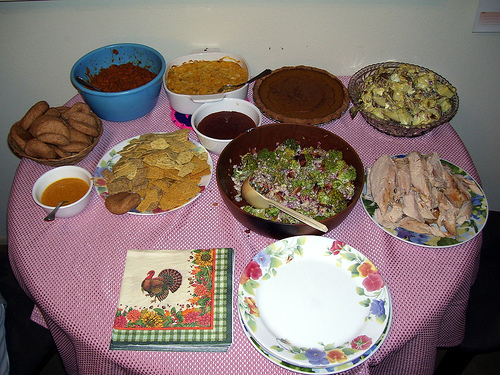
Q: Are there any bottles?
A: No, there are no bottles.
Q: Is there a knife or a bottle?
A: No, there are no bottles or knives.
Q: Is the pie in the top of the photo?
A: Yes, the pie is in the top of the image.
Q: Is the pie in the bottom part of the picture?
A: No, the pie is in the top of the image.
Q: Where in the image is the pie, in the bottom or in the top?
A: The pie is in the top of the image.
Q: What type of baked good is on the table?
A: The food is a pie.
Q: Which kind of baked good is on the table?
A: The food is a pie.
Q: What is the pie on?
A: The pie is on the table.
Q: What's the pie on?
A: The pie is on the table.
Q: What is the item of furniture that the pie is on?
A: The piece of furniture is a table.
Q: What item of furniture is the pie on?
A: The pie is on the table.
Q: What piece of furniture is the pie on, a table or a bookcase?
A: The pie is on a table.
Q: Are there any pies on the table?
A: Yes, there is a pie on the table.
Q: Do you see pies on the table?
A: Yes, there is a pie on the table.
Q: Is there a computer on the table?
A: No, there is a pie on the table.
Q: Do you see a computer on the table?
A: No, there is a pie on the table.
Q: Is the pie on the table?
A: Yes, the pie is on the table.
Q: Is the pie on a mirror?
A: No, the pie is on the table.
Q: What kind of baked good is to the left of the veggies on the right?
A: The food is a pie.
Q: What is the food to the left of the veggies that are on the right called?
A: The food is a pie.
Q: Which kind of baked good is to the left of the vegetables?
A: The food is a pie.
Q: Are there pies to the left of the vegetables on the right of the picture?
A: Yes, there is a pie to the left of the vegetables.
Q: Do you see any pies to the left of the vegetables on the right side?
A: Yes, there is a pie to the left of the vegetables.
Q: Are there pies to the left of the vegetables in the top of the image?
A: Yes, there is a pie to the left of the vegetables.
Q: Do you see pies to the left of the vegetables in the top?
A: Yes, there is a pie to the left of the vegetables.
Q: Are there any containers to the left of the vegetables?
A: No, there is a pie to the left of the vegetables.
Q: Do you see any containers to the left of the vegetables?
A: No, there is a pie to the left of the vegetables.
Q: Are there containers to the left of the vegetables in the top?
A: No, there is a pie to the left of the vegetables.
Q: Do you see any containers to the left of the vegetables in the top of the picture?
A: No, there is a pie to the left of the vegetables.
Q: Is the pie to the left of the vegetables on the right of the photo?
A: Yes, the pie is to the left of the vegetables.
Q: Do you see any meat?
A: Yes, there is meat.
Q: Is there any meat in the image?
A: Yes, there is meat.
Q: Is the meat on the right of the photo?
A: Yes, the meat is on the right of the image.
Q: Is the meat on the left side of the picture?
A: No, the meat is on the right of the image.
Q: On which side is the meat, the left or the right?
A: The meat is on the right of the image.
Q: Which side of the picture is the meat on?
A: The meat is on the right of the image.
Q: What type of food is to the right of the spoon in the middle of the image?
A: The food is meat.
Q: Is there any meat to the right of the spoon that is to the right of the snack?
A: Yes, there is meat to the right of the spoon.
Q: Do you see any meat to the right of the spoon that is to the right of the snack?
A: Yes, there is meat to the right of the spoon.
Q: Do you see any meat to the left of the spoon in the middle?
A: No, the meat is to the right of the spoon.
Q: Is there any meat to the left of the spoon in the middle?
A: No, the meat is to the right of the spoon.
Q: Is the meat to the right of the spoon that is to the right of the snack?
A: Yes, the meat is to the right of the spoon.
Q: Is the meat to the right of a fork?
A: No, the meat is to the right of the spoon.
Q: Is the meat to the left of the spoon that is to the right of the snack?
A: No, the meat is to the right of the spoon.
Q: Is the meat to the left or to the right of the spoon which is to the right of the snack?
A: The meat is to the right of the spoon.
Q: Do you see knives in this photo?
A: No, there are no knives.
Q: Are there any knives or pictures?
A: No, there are no knives or pictures.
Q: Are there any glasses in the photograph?
A: No, there are no glasses.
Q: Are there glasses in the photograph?
A: No, there are no glasses.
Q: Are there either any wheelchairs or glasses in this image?
A: No, there are no glasses or wheelchairs.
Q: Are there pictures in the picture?
A: No, there are no pictures.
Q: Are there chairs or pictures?
A: No, there are no pictures or chairs.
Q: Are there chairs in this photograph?
A: No, there are no chairs.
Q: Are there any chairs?
A: No, there are no chairs.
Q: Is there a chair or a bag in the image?
A: No, there are no chairs or bags.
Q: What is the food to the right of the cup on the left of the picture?
A: The food is a snack.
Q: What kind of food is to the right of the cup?
A: The food is a snack.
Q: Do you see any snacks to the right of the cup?
A: Yes, there is a snack to the right of the cup.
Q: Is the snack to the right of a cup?
A: Yes, the snack is to the right of a cup.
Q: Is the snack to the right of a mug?
A: No, the snack is to the right of a cup.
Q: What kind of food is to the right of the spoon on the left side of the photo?
A: The food is a snack.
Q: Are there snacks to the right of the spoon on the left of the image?
A: Yes, there is a snack to the right of the spoon.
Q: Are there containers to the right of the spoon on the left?
A: No, there is a snack to the right of the spoon.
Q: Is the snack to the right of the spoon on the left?
A: Yes, the snack is to the right of the spoon.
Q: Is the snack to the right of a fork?
A: No, the snack is to the right of the spoon.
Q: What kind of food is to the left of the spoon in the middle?
A: The food is a snack.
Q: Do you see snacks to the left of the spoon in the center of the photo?
A: Yes, there is a snack to the left of the spoon.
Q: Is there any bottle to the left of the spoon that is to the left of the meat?
A: No, there is a snack to the left of the spoon.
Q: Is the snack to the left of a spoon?
A: Yes, the snack is to the left of a spoon.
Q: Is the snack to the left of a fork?
A: No, the snack is to the left of a spoon.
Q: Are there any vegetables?
A: Yes, there are vegetables.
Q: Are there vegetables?
A: Yes, there are vegetables.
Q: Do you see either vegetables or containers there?
A: Yes, there are vegetables.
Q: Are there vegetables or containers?
A: Yes, there are vegetables.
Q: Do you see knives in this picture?
A: No, there are no knives.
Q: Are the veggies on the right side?
A: Yes, the veggies are on the right of the image.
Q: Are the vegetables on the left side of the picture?
A: No, the vegetables are on the right of the image.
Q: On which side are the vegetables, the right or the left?
A: The vegetables are on the right of the image.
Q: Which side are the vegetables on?
A: The vegetables are on the right of the image.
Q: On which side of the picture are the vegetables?
A: The vegetables are on the right of the image.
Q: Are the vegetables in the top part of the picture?
A: Yes, the vegetables are in the top of the image.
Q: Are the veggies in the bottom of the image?
A: No, the veggies are in the top of the image.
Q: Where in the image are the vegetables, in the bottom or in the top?
A: The vegetables are in the top of the image.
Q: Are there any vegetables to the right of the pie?
A: Yes, there are vegetables to the right of the pie.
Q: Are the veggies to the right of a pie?
A: Yes, the veggies are to the right of a pie.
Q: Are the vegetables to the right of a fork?
A: No, the vegetables are to the right of a pie.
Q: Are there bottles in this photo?
A: No, there are no bottles.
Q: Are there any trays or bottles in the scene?
A: No, there are no bottles or trays.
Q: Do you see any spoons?
A: Yes, there is a spoon.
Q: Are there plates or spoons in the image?
A: Yes, there is a spoon.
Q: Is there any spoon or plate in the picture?
A: Yes, there is a spoon.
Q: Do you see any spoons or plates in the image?
A: Yes, there is a spoon.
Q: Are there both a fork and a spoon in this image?
A: No, there is a spoon but no forks.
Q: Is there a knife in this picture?
A: No, there are no knives.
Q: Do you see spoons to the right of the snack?
A: Yes, there is a spoon to the right of the snack.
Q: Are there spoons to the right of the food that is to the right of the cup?
A: Yes, there is a spoon to the right of the snack.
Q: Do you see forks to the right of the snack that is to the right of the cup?
A: No, there is a spoon to the right of the snack.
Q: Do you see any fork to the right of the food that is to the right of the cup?
A: No, there is a spoon to the right of the snack.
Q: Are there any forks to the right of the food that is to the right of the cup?
A: No, there is a spoon to the right of the snack.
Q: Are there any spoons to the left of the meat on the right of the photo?
A: Yes, there is a spoon to the left of the meat.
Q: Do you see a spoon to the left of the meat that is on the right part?
A: Yes, there is a spoon to the left of the meat.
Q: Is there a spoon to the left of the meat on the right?
A: Yes, there is a spoon to the left of the meat.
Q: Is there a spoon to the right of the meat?
A: No, the spoon is to the left of the meat.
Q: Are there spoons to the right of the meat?
A: No, the spoon is to the left of the meat.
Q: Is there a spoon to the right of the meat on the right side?
A: No, the spoon is to the left of the meat.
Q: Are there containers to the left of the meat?
A: No, there is a spoon to the left of the meat.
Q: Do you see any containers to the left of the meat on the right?
A: No, there is a spoon to the left of the meat.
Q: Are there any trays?
A: No, there are no trays.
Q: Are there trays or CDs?
A: No, there are no trays or cds.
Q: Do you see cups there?
A: Yes, there is a cup.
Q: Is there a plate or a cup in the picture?
A: Yes, there is a cup.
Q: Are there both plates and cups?
A: Yes, there are both a cup and a plate.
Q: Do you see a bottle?
A: No, there are no bottles.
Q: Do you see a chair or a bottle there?
A: No, there are no bottles or chairs.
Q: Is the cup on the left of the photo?
A: Yes, the cup is on the left of the image.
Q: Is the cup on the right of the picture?
A: No, the cup is on the left of the image.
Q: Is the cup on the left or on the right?
A: The cup is on the left of the image.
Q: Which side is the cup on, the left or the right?
A: The cup is on the left of the image.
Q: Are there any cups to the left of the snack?
A: Yes, there is a cup to the left of the snack.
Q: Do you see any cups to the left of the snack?
A: Yes, there is a cup to the left of the snack.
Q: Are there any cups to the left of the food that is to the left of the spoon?
A: Yes, there is a cup to the left of the snack.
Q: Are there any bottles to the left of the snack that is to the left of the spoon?
A: No, there is a cup to the left of the snack.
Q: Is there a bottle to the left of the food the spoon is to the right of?
A: No, there is a cup to the left of the snack.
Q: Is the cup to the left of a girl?
A: No, the cup is to the left of a snack.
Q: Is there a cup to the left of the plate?
A: Yes, there is a cup to the left of the plate.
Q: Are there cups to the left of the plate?
A: Yes, there is a cup to the left of the plate.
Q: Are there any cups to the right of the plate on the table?
A: No, the cup is to the left of the plate.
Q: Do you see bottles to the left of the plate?
A: No, there is a cup to the left of the plate.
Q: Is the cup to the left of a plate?
A: Yes, the cup is to the left of a plate.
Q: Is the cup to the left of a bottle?
A: No, the cup is to the left of a plate.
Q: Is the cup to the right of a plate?
A: No, the cup is to the left of a plate.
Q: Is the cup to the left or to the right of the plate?
A: The cup is to the left of the plate.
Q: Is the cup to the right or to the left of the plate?
A: The cup is to the left of the plate.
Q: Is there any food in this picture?
A: Yes, there is food.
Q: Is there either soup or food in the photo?
A: Yes, there is food.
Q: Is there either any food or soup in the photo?
A: Yes, there is food.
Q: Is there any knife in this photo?
A: No, there are no knives.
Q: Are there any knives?
A: No, there are no knives.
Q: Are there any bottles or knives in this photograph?
A: No, there are no knives or bottles.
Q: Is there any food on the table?
A: Yes, there is food on the table.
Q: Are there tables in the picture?
A: Yes, there is a table.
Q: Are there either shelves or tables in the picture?
A: Yes, there is a table.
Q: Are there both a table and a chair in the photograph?
A: No, there is a table but no chairs.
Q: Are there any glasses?
A: No, there are no glasses.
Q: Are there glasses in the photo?
A: No, there are no glasses.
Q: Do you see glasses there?
A: No, there are no glasses.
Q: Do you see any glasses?
A: No, there are no glasses.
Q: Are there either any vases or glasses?
A: No, there are no glasses or vases.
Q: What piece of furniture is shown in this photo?
A: The piece of furniture is a table.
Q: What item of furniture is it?
A: The piece of furniture is a table.